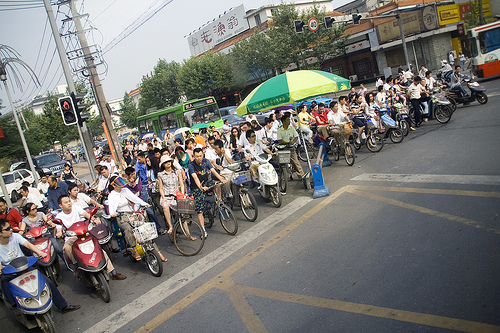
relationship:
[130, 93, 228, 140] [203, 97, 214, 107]
bus with lights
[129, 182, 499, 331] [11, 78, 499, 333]
lines on road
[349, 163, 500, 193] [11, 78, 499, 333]
markings on road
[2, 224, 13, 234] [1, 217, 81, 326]
sunglasses on person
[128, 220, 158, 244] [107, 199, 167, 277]
basket on bike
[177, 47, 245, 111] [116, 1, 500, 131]
trees near buildings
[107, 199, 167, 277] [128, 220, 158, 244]
bike has basket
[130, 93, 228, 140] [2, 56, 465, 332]
bus behind people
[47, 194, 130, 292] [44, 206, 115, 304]
man on bike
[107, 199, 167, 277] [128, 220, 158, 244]
bike with basket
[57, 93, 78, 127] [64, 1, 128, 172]
light on pole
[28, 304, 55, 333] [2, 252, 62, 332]
wheel of scooter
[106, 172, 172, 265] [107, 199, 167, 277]
woman on bike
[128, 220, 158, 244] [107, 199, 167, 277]
basket on front of bike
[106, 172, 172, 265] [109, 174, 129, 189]
woman with hat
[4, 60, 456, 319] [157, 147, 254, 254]
group of cyclist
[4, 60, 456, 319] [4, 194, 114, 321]
group of motorcyclists